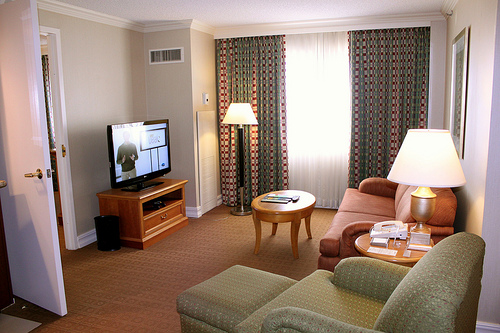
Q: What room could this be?
A: It is a living room.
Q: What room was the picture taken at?
A: It was taken at the living room.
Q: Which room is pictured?
A: It is a living room.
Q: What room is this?
A: It is a living room.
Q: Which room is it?
A: It is a living room.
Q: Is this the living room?
A: Yes, it is the living room.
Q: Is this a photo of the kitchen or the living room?
A: It is showing the living room.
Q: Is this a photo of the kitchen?
A: No, the picture is showing the living room.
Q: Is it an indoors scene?
A: Yes, it is indoors.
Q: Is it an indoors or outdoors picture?
A: It is indoors.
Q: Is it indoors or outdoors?
A: It is indoors.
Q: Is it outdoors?
A: No, it is indoors.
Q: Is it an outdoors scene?
A: No, it is indoors.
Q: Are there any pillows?
A: No, there are no pillows.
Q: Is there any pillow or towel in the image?
A: No, there are no pillows or towels.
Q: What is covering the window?
A: The curtain is covering the window.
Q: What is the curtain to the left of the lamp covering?
A: The curtain is covering the window.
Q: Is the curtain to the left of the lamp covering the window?
A: Yes, the curtain is covering the window.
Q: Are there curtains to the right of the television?
A: Yes, there is a curtain to the right of the television.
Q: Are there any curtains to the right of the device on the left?
A: Yes, there is a curtain to the right of the television.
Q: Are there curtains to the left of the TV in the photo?
A: No, the curtain is to the right of the TV.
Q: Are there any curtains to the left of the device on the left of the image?
A: No, the curtain is to the right of the TV.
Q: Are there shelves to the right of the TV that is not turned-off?
A: No, there is a curtain to the right of the TV.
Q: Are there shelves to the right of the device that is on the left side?
A: No, there is a curtain to the right of the TV.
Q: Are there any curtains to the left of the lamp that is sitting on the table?
A: Yes, there is a curtain to the left of the lamp.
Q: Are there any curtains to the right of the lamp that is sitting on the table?
A: No, the curtain is to the left of the lamp.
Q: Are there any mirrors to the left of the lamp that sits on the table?
A: No, there is a curtain to the left of the lamp.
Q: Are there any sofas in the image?
A: Yes, there is a sofa.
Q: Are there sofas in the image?
A: Yes, there is a sofa.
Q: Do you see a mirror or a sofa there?
A: Yes, there is a sofa.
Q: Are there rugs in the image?
A: No, there are no rugs.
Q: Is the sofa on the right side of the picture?
A: Yes, the sofa is on the right of the image.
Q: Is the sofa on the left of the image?
A: No, the sofa is on the right of the image.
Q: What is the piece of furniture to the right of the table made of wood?
A: The piece of furniture is a sofa.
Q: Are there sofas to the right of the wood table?
A: Yes, there is a sofa to the right of the table.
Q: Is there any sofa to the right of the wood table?
A: Yes, there is a sofa to the right of the table.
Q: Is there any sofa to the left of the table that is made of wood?
A: No, the sofa is to the right of the table.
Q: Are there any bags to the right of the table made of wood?
A: No, there is a sofa to the right of the table.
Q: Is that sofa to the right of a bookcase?
A: No, the sofa is to the right of a table.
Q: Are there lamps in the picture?
A: Yes, there is a lamp.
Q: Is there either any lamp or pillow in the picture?
A: Yes, there is a lamp.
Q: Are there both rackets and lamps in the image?
A: No, there is a lamp but no rackets.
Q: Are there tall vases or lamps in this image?
A: Yes, there is a tall lamp.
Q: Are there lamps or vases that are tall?
A: Yes, the lamp is tall.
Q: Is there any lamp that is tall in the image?
A: Yes, there is a tall lamp.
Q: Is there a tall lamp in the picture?
A: Yes, there is a tall lamp.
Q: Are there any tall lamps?
A: Yes, there is a tall lamp.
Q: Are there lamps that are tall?
A: Yes, there is a lamp that is tall.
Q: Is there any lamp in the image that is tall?
A: Yes, there is a lamp that is tall.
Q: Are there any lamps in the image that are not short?
A: Yes, there is a tall lamp.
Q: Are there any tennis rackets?
A: No, there are no tennis rackets.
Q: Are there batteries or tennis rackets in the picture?
A: No, there are no tennis rackets or batteries.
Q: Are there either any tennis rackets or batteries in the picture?
A: No, there are no tennis rackets or batteries.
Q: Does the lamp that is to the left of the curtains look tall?
A: Yes, the lamp is tall.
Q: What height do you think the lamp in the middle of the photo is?
A: The lamp is tall.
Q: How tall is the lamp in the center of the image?
A: The lamp is tall.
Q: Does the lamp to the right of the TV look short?
A: No, the lamp is tall.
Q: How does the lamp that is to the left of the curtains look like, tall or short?
A: The lamp is tall.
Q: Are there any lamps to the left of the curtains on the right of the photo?
A: Yes, there is a lamp to the left of the curtains.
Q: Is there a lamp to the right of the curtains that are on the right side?
A: No, the lamp is to the left of the curtains.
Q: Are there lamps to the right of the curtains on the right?
A: No, the lamp is to the left of the curtains.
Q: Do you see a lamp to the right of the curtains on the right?
A: No, the lamp is to the left of the curtains.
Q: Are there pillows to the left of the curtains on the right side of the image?
A: No, there is a lamp to the left of the curtains.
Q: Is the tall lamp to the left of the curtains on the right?
A: Yes, the lamp is to the left of the curtains.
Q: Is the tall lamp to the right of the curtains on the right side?
A: No, the lamp is to the left of the curtains.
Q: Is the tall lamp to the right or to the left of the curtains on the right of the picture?
A: The lamp is to the left of the curtains.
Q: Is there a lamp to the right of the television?
A: Yes, there is a lamp to the right of the television.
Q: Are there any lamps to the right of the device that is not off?
A: Yes, there is a lamp to the right of the television.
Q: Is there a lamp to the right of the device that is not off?
A: Yes, there is a lamp to the right of the television.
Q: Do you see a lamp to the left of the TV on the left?
A: No, the lamp is to the right of the TV.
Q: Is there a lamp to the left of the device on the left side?
A: No, the lamp is to the right of the TV.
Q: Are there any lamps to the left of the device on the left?
A: No, the lamp is to the right of the TV.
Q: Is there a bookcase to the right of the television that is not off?
A: No, there is a lamp to the right of the television.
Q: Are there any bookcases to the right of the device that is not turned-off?
A: No, there is a lamp to the right of the television.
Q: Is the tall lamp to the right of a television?
A: Yes, the lamp is to the right of a television.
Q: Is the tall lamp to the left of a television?
A: No, the lamp is to the right of a television.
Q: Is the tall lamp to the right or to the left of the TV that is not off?
A: The lamp is to the right of the television.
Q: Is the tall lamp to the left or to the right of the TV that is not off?
A: The lamp is to the right of the television.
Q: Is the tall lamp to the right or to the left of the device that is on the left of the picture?
A: The lamp is to the right of the television.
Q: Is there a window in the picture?
A: Yes, there is a window.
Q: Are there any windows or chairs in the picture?
A: Yes, there is a window.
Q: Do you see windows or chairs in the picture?
A: Yes, there is a window.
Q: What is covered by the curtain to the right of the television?
A: The window is covered by the curtain.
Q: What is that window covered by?
A: The window is covered by the curtain.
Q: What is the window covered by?
A: The window is covered by the curtain.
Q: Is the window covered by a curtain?
A: Yes, the window is covered by a curtain.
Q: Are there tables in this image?
A: Yes, there is a table.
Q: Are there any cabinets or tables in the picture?
A: Yes, there is a table.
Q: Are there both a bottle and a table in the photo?
A: No, there is a table but no bottles.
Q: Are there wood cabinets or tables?
A: Yes, there is a wood table.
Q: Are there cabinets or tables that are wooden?
A: Yes, the table is wooden.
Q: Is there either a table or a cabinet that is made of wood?
A: Yes, the table is made of wood.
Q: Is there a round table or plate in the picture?
A: Yes, there is a round table.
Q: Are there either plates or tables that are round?
A: Yes, the table is round.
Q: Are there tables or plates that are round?
A: Yes, the table is round.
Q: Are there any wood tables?
A: Yes, there is a table that is made of wood.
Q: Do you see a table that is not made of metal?
A: Yes, there is a table that is made of wood.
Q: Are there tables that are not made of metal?
A: Yes, there is a table that is made of wood.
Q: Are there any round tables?
A: Yes, there is a round table.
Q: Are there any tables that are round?
A: Yes, there is a table that is round.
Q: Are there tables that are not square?
A: Yes, there is a round table.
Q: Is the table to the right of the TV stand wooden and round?
A: Yes, the table is wooden and round.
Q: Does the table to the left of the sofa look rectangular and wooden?
A: No, the table is wooden but round.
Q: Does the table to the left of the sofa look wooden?
A: Yes, the table is wooden.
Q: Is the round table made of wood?
A: Yes, the table is made of wood.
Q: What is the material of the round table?
A: The table is made of wood.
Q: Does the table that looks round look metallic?
A: No, the table is wooden.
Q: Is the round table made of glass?
A: No, the table is made of wood.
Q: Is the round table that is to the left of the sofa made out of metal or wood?
A: The table is made of wood.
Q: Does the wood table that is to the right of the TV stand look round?
A: Yes, the table is round.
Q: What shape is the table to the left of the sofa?
A: The table is round.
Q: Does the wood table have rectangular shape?
A: No, the table is round.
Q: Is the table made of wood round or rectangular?
A: The table is round.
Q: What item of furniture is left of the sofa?
A: The piece of furniture is a table.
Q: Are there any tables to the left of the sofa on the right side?
A: Yes, there is a table to the left of the sofa.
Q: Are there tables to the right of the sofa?
A: No, the table is to the left of the sofa.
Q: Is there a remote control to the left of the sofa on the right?
A: No, there is a table to the left of the sofa.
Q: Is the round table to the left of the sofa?
A: Yes, the table is to the left of the sofa.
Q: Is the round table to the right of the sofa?
A: No, the table is to the left of the sofa.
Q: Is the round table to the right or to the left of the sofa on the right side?
A: The table is to the left of the sofa.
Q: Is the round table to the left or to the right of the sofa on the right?
A: The table is to the left of the sofa.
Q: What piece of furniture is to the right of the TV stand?
A: The piece of furniture is a table.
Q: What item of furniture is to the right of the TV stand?
A: The piece of furniture is a table.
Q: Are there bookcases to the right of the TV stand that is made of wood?
A: No, there is a table to the right of the TV stand.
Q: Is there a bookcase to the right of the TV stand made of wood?
A: No, there is a table to the right of the TV stand.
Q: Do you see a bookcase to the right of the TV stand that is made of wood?
A: No, there is a table to the right of the TV stand.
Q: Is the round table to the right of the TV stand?
A: Yes, the table is to the right of the TV stand.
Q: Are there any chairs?
A: Yes, there is a chair.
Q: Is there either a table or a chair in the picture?
A: Yes, there is a chair.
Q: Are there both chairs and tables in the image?
A: Yes, there are both a chair and a table.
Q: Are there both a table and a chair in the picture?
A: Yes, there are both a chair and a table.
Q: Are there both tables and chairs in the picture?
A: Yes, there are both a chair and a table.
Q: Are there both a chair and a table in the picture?
A: Yes, there are both a chair and a table.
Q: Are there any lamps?
A: Yes, there is a lamp.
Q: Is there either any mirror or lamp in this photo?
A: Yes, there is a lamp.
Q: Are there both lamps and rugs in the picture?
A: No, there is a lamp but no rugs.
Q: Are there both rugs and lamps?
A: No, there is a lamp but no rugs.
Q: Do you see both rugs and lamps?
A: No, there is a lamp but no rugs.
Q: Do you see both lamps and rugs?
A: No, there is a lamp but no rugs.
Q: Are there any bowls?
A: No, there are no bowls.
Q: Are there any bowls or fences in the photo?
A: No, there are no bowls or fences.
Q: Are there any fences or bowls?
A: No, there are no bowls or fences.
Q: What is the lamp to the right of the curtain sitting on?
A: The lamp is sitting on the table.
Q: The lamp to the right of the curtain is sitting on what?
A: The lamp is sitting on the table.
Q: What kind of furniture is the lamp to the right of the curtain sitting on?
A: The lamp is sitting on the table.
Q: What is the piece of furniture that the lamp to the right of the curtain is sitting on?
A: The piece of furniture is a table.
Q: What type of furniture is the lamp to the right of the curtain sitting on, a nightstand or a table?
A: The lamp is sitting on a table.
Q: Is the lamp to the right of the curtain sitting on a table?
A: Yes, the lamp is sitting on a table.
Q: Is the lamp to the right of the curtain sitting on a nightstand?
A: No, the lamp is sitting on a table.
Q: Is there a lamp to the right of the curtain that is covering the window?
A: Yes, there is a lamp to the right of the curtain.